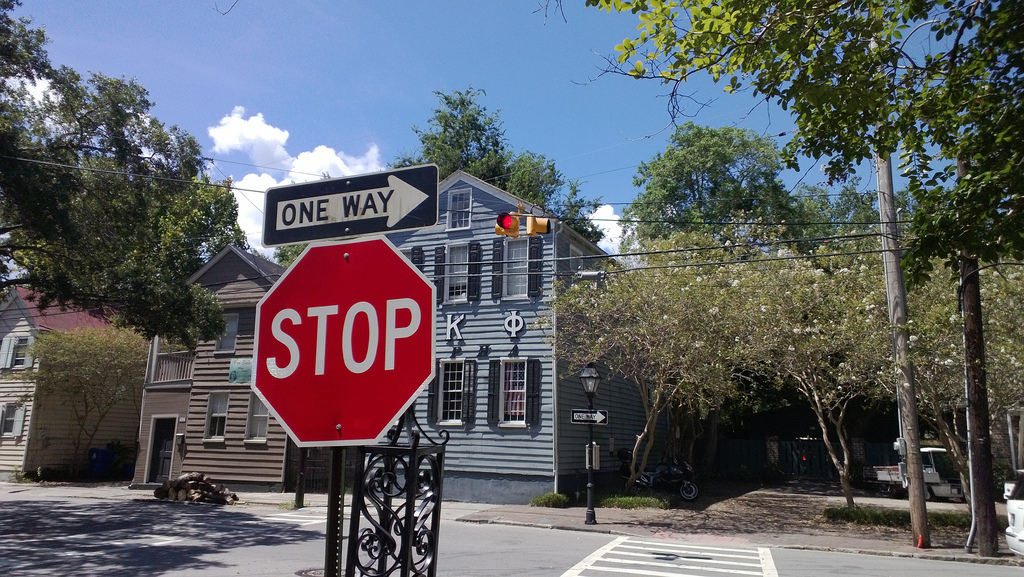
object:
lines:
[559, 535, 779, 576]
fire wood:
[154, 472, 239, 505]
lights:
[495, 204, 551, 239]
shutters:
[434, 242, 480, 303]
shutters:
[487, 359, 539, 425]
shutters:
[427, 358, 476, 423]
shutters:
[492, 236, 544, 298]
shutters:
[399, 246, 423, 273]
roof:
[0, 286, 120, 333]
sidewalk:
[458, 482, 1022, 567]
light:
[580, 362, 603, 525]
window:
[499, 360, 526, 424]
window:
[502, 238, 528, 298]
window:
[446, 246, 467, 302]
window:
[440, 361, 464, 422]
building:
[363, 169, 678, 504]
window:
[450, 190, 469, 229]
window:
[250, 393, 269, 439]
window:
[208, 392, 230, 439]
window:
[218, 313, 240, 351]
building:
[126, 244, 357, 493]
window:
[2, 403, 16, 435]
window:
[13, 337, 28, 367]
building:
[0, 287, 147, 483]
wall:
[24, 363, 144, 471]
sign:
[249, 234, 437, 448]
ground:
[0, 482, 1024, 577]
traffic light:
[495, 211, 520, 239]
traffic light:
[526, 215, 551, 237]